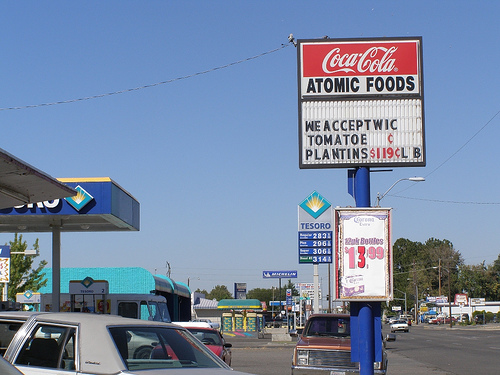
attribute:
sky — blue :
[20, 3, 499, 312]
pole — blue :
[348, 171, 379, 371]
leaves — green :
[392, 239, 495, 299]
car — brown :
[297, 312, 390, 370]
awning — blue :
[2, 176, 144, 234]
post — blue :
[353, 165, 385, 372]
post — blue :
[348, 167, 388, 373]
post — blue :
[342, 166, 384, 374]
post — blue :
[348, 171, 383, 367]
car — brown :
[290, 316, 387, 374]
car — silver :
[5, 313, 253, 373]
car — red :
[172, 325, 229, 367]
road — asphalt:
[389, 325, 484, 373]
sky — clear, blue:
[146, 118, 263, 227]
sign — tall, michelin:
[261, 265, 299, 285]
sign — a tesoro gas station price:
[296, 190, 336, 266]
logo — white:
[318, 44, 399, 75]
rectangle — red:
[297, 39, 418, 79]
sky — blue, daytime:
[1, 0, 201, 70]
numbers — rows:
[311, 228, 332, 264]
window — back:
[104, 326, 220, 371]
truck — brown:
[284, 310, 391, 372]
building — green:
[26, 263, 194, 323]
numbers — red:
[372, 145, 393, 160]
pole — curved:
[381, 176, 410, 195]